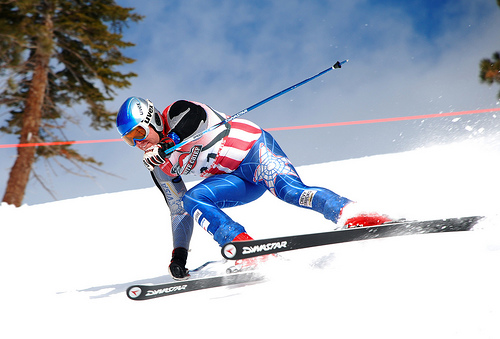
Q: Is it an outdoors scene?
A: Yes, it is outdoors.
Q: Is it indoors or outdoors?
A: It is outdoors.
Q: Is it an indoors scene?
A: No, it is outdoors.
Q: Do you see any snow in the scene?
A: Yes, there is snow.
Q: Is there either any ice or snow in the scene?
A: Yes, there is snow.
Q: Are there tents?
A: No, there are no tents.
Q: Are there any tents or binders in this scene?
A: No, there are no tents or binders.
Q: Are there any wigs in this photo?
A: No, there are no wigs.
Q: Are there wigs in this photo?
A: No, there are no wigs.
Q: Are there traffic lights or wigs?
A: No, there are no wigs or traffic lights.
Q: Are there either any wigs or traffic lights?
A: No, there are no wigs or traffic lights.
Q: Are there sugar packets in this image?
A: No, there are no sugar packets.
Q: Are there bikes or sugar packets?
A: No, there are no sugar packets or bikes.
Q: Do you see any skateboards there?
A: No, there are no skateboards.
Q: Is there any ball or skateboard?
A: No, there are no skateboards or balls.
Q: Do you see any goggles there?
A: Yes, there are goggles.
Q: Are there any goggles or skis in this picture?
A: Yes, there are goggles.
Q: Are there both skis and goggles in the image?
A: Yes, there are both goggles and skis.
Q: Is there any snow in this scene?
A: Yes, there is snow.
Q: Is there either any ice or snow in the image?
A: Yes, there is snow.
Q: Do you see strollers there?
A: No, there are no strollers.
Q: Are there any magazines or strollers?
A: No, there are no strollers or magazines.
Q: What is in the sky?
A: The clouds are in the sky.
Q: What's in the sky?
A: The clouds are in the sky.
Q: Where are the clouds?
A: The clouds are in the sky.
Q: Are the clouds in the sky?
A: Yes, the clouds are in the sky.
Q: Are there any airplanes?
A: No, there are no airplanes.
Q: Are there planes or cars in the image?
A: No, there are no planes or cars.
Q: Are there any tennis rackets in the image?
A: No, there are no tennis rackets.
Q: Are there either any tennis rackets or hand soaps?
A: No, there are no tennis rackets or hand soaps.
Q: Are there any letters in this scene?
A: Yes, there are letters.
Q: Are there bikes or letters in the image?
A: Yes, there are letters.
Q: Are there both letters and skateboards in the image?
A: No, there are letters but no skateboards.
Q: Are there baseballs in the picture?
A: No, there are no baseballs.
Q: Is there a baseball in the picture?
A: No, there are no baseballs.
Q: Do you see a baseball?
A: No, there are no baseballs.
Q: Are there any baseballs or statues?
A: No, there are no baseballs or statues.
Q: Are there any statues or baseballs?
A: No, there are no baseballs or statues.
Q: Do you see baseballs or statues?
A: No, there are no baseballs or statues.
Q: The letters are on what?
A: The letters are on the ski.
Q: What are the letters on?
A: The letters are on the ski.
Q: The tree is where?
A: The tree is on the mountain.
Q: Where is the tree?
A: The tree is on the mountain.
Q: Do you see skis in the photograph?
A: Yes, there are skis.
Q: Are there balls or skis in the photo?
A: Yes, there are skis.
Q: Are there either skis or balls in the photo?
A: Yes, there are skis.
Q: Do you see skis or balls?
A: Yes, there are skis.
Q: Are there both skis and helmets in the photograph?
A: Yes, there are both skis and a helmet.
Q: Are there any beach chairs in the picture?
A: No, there are no beach chairs.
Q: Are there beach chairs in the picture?
A: No, there are no beach chairs.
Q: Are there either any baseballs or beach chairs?
A: No, there are no beach chairs or baseballs.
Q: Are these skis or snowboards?
A: These are skis.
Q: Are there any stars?
A: Yes, there is a star.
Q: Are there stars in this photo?
A: Yes, there is a star.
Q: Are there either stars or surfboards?
A: Yes, there is a star.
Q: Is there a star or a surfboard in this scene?
A: Yes, there is a star.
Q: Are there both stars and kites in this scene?
A: No, there is a star but no kites.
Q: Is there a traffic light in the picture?
A: No, there are no traffic lights.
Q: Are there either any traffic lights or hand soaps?
A: No, there are no traffic lights or hand soaps.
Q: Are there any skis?
A: Yes, there are skis.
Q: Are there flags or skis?
A: Yes, there are skis.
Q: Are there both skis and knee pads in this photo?
A: No, there are skis but no knee pads.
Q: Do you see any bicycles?
A: No, there are no bicycles.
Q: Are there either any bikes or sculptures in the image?
A: No, there are no bikes or sculptures.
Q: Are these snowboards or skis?
A: These are skis.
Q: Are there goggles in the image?
A: Yes, there are goggles.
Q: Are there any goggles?
A: Yes, there are goggles.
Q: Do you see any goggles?
A: Yes, there are goggles.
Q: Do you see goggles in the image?
A: Yes, there are goggles.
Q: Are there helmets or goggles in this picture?
A: Yes, there are goggles.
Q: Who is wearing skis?
A: The man is wearing skis.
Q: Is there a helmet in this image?
A: Yes, there is a helmet.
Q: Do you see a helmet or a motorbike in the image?
A: Yes, there is a helmet.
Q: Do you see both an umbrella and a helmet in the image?
A: No, there is a helmet but no umbrellas.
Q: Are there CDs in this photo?
A: No, there are no cds.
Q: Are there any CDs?
A: No, there are no cds.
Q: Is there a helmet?
A: Yes, there is a helmet.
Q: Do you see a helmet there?
A: Yes, there is a helmet.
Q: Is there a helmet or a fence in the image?
A: Yes, there is a helmet.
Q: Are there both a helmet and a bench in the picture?
A: No, there is a helmet but no benches.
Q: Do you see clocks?
A: No, there are no clocks.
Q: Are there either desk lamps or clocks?
A: No, there are no clocks or desk lamps.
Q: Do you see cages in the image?
A: No, there are no cages.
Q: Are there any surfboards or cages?
A: No, there are no cages or surfboards.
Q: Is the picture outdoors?
A: Yes, the picture is outdoors.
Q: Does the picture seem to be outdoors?
A: Yes, the picture is outdoors.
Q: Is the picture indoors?
A: No, the picture is outdoors.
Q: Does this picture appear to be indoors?
A: No, the picture is outdoors.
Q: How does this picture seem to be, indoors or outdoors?
A: The picture is outdoors.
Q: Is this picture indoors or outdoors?
A: The picture is outdoors.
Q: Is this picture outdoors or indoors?
A: The picture is outdoors.